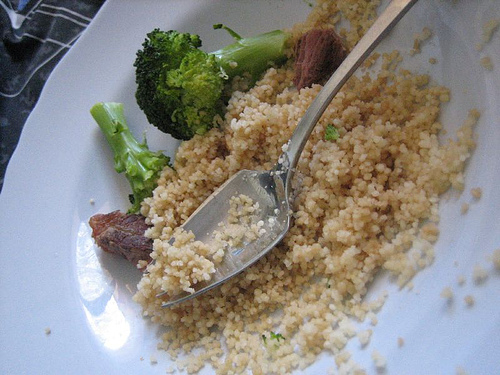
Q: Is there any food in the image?
A: Yes, there is food.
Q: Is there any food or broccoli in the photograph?
A: Yes, there is food.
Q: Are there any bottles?
A: No, there are no bottles.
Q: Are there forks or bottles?
A: No, there are no bottles or forks.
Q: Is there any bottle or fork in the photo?
A: No, there are no bottles or forks.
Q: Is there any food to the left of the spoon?
A: Yes, there is food to the left of the spoon.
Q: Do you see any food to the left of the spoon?
A: Yes, there is food to the left of the spoon.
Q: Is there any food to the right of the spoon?
A: No, the food is to the left of the spoon.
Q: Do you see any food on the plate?
A: Yes, there is food on the plate.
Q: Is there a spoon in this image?
A: Yes, there is a spoon.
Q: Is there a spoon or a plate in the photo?
A: Yes, there is a spoon.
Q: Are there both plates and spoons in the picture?
A: Yes, there are both a spoon and a plate.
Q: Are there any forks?
A: No, there are no forks.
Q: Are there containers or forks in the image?
A: No, there are no forks or containers.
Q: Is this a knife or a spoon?
A: This is a spoon.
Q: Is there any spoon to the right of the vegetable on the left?
A: Yes, there is a spoon to the right of the vegetable.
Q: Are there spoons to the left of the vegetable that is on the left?
A: No, the spoon is to the right of the vegetable.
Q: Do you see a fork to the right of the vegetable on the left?
A: No, there is a spoon to the right of the vegetable.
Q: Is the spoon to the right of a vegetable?
A: Yes, the spoon is to the right of a vegetable.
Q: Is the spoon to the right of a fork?
A: No, the spoon is to the right of a vegetable.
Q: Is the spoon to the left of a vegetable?
A: No, the spoon is to the right of a vegetable.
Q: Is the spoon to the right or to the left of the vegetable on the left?
A: The spoon is to the right of the vegetable.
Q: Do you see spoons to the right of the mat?
A: Yes, there is a spoon to the right of the mat.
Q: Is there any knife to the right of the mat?
A: No, there is a spoon to the right of the mat.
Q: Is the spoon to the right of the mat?
A: Yes, the spoon is to the right of the mat.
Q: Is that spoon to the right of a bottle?
A: No, the spoon is to the right of the mat.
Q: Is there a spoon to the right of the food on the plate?
A: Yes, there is a spoon to the right of the food.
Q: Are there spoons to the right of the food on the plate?
A: Yes, there is a spoon to the right of the food.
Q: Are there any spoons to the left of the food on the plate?
A: No, the spoon is to the right of the food.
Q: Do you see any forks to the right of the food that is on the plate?
A: No, there is a spoon to the right of the food.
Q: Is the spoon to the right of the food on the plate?
A: Yes, the spoon is to the right of the food.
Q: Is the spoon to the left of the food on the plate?
A: No, the spoon is to the right of the food.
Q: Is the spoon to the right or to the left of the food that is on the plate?
A: The spoon is to the right of the food.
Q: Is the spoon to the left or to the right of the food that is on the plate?
A: The spoon is to the right of the food.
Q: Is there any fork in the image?
A: No, there are no forks.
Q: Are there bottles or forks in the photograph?
A: No, there are no forks or bottles.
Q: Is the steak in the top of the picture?
A: Yes, the steak is in the top of the image.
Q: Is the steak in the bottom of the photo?
A: No, the steak is in the top of the image.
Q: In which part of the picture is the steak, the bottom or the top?
A: The steak is in the top of the image.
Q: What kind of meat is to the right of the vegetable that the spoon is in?
A: The meat is a steak.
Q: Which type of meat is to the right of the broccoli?
A: The meat is a steak.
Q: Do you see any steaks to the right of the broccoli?
A: Yes, there is a steak to the right of the broccoli.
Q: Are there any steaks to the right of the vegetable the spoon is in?
A: Yes, there is a steak to the right of the broccoli.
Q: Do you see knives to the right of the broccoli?
A: No, there is a steak to the right of the broccoli.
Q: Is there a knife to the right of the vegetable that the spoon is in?
A: No, there is a steak to the right of the broccoli.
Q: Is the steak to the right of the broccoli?
A: Yes, the steak is to the right of the broccoli.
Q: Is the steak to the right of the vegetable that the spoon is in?
A: Yes, the steak is to the right of the broccoli.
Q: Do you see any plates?
A: Yes, there is a plate.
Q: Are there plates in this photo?
A: Yes, there is a plate.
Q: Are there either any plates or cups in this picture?
A: Yes, there is a plate.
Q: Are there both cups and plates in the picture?
A: No, there is a plate but no cups.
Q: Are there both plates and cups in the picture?
A: No, there is a plate but no cups.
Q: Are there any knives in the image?
A: No, there are no knives.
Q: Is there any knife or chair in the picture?
A: No, there are no knives or chairs.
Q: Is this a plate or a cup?
A: This is a plate.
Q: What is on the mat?
A: The plate is on the mat.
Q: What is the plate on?
A: The plate is on the mat.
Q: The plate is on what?
A: The plate is on the mat.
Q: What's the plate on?
A: The plate is on the mat.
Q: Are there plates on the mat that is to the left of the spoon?
A: Yes, there is a plate on the mat.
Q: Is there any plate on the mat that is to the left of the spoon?
A: Yes, there is a plate on the mat.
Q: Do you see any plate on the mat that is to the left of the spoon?
A: Yes, there is a plate on the mat.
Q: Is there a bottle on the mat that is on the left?
A: No, there is a plate on the mat.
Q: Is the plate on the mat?
A: Yes, the plate is on the mat.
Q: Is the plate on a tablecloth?
A: No, the plate is on the mat.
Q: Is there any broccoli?
A: Yes, there is broccoli.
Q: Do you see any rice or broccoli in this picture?
A: Yes, there is broccoli.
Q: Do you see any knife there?
A: No, there are no knives.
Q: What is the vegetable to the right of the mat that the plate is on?
A: The vegetable is broccoli.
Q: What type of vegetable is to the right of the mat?
A: The vegetable is broccoli.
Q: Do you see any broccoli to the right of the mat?
A: Yes, there is broccoli to the right of the mat.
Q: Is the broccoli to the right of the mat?
A: Yes, the broccoli is to the right of the mat.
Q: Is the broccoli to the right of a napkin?
A: No, the broccoli is to the right of the mat.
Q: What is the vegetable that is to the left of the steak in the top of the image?
A: The vegetable is broccoli.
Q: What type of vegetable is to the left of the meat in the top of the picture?
A: The vegetable is broccoli.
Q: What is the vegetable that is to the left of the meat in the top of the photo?
A: The vegetable is broccoli.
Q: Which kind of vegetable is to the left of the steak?
A: The vegetable is broccoli.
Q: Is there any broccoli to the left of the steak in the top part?
A: Yes, there is broccoli to the left of the steak.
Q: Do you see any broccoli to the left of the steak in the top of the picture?
A: Yes, there is broccoli to the left of the steak.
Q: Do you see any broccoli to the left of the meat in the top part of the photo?
A: Yes, there is broccoli to the left of the steak.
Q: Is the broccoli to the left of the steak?
A: Yes, the broccoli is to the left of the steak.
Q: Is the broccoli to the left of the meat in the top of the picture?
A: Yes, the broccoli is to the left of the steak.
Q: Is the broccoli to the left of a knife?
A: No, the broccoli is to the left of the steak.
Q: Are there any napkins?
A: No, there are no napkins.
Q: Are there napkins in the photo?
A: No, there are no napkins.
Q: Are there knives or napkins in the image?
A: No, there are no napkins or knives.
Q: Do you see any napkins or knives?
A: No, there are no napkins or knives.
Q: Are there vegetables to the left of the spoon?
A: Yes, there is a vegetable to the left of the spoon.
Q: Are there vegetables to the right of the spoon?
A: No, the vegetable is to the left of the spoon.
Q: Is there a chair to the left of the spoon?
A: No, there is a vegetable to the left of the spoon.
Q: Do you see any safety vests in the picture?
A: No, there are no safety vests.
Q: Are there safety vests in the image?
A: No, there are no safety vests.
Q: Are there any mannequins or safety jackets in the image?
A: No, there are no safety jackets or mannequins.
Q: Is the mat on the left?
A: Yes, the mat is on the left of the image.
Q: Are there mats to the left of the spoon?
A: Yes, there is a mat to the left of the spoon.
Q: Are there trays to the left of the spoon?
A: No, there is a mat to the left of the spoon.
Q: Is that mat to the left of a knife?
A: No, the mat is to the left of a spoon.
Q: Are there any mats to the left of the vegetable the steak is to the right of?
A: Yes, there is a mat to the left of the broccoli.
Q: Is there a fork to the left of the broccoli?
A: No, there is a mat to the left of the broccoli.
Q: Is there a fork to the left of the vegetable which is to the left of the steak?
A: No, there is a mat to the left of the broccoli.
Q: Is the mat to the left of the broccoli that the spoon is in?
A: Yes, the mat is to the left of the broccoli.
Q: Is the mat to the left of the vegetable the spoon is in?
A: Yes, the mat is to the left of the broccoli.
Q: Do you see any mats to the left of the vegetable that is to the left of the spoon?
A: Yes, there is a mat to the left of the vegetable.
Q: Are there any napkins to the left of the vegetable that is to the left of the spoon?
A: No, there is a mat to the left of the vegetable.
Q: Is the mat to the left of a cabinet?
A: No, the mat is to the left of a vegetable.